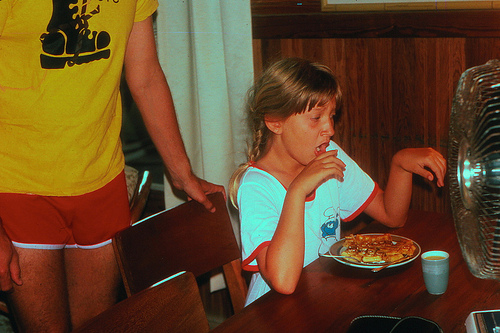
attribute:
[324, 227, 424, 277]
plate — food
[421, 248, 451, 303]
cup — beverage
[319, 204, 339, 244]
shirt — blue 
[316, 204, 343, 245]
character — blue 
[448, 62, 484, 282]
fan — metal 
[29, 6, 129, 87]
blade —  black roller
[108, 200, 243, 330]
chair — wooden 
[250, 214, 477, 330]
table — wooden 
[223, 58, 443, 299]
girl — little , young 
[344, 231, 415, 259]
waffles — breakfast 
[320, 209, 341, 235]
print — hiking boot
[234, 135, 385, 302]
shirt — girl's  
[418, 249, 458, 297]
cup — small 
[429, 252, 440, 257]
coffee — creamy 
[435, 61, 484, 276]
fan — large electric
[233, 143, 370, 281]
shirt — girl's  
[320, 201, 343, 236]
smurf — blue  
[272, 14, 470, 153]
wood — lacquered wood 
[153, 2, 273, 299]
curtain — heavy white 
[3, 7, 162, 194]
shirt — yellow 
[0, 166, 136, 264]
shorts — white biking, red 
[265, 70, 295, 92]
hair — braids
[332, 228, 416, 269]
plate — glass 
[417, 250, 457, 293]
cup — white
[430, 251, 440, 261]
beverage — some type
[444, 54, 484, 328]
tabletop fan — electric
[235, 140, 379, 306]
pajamas — white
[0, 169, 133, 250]
shorts — red boy , white, red, 80s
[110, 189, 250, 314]
chair — brown, real wood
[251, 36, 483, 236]
panneling — wood, brown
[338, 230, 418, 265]
meal — fun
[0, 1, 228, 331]
brother — older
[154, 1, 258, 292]
curtain — white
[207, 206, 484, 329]
table — wooden, cluttered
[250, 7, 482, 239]
panel — wooden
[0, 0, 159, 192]
t-shirt — yellow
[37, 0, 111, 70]
print — black, graphic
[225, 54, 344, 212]
hair — long blond, blonde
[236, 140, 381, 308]
t-shirt — red, white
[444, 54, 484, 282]
fan — silver